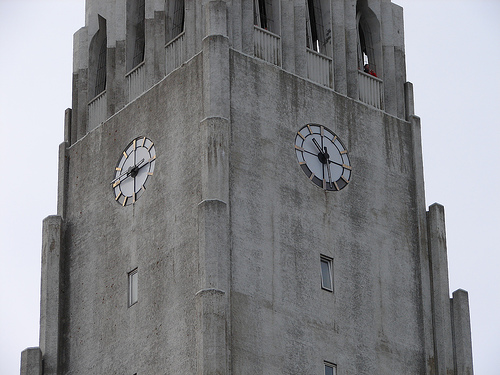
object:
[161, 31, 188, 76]
railing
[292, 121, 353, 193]
clock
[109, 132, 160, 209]
clock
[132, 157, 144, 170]
hand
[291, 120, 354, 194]
clock face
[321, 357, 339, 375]
small window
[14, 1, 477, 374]
tower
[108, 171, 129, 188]
hand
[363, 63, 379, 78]
person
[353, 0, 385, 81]
window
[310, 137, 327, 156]
hand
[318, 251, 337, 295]
window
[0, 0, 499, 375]
sky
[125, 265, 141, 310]
window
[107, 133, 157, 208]
clock face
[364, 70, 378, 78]
red object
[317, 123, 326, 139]
number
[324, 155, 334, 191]
hand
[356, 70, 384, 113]
balcony